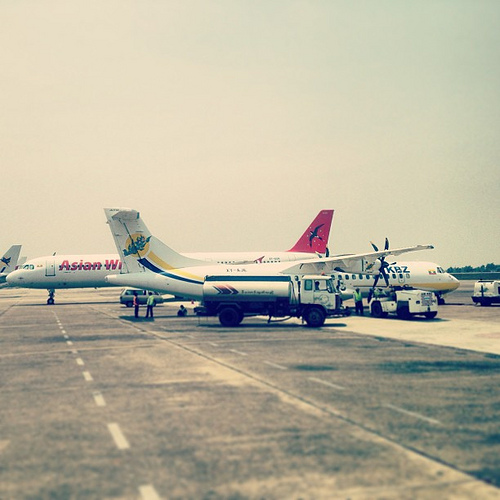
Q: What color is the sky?
A: Grey.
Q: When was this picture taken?
A: During the day.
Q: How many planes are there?
A: Three.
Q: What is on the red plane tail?
A: A bird.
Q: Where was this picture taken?
A: An airport.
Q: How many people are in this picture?
A: Four.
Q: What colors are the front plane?
A: White, yellow, and black.